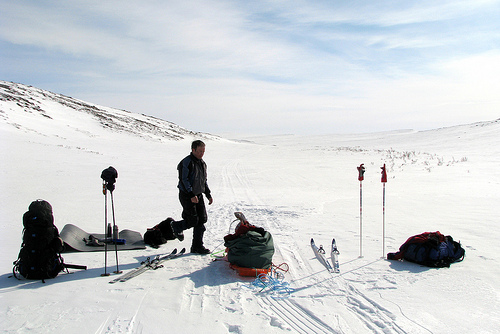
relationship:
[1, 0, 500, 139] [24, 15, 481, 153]
cloud in sky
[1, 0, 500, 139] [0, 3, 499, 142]
cloud in sky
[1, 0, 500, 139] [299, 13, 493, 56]
cloud in sky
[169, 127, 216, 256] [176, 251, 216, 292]
man walks on snow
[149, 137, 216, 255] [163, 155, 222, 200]
man wearing coat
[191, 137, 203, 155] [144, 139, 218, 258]
hair on man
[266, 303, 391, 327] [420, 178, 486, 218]
track in snow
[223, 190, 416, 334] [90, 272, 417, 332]
track in snow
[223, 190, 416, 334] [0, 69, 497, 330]
track in snow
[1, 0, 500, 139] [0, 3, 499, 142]
cloud on sky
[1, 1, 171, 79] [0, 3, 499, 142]
cloud on sky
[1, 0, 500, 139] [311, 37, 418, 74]
cloud on sky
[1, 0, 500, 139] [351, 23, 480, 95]
cloud in sky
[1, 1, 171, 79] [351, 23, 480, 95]
cloud in sky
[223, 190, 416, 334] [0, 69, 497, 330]
track are on snow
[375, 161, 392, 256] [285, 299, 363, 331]
pole on snow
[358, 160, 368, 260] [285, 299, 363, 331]
pole on snow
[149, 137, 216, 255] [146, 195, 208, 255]
man with pants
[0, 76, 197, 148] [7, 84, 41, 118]
ground on hill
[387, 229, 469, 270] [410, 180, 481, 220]
bag lying on snow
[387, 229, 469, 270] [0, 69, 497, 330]
bag on snow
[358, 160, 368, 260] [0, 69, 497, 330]
pole stuck in snow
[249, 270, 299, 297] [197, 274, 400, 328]
rope on ground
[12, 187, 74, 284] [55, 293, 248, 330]
pack sitting in snow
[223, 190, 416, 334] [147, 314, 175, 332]
track on snow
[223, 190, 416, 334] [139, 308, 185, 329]
track on snow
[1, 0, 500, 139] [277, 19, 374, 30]
cloud in sky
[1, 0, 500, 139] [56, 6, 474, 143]
cloud in sky